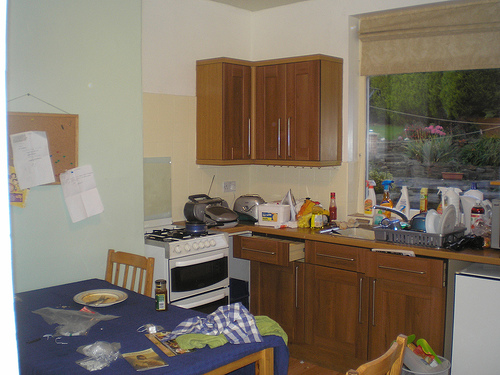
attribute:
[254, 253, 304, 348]
cupboard — wooden 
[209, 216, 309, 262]
cupboard — wooden 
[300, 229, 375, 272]
cupboard — wooden 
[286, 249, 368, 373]
cupboard — wooden 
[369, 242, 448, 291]
cupboard — wooden 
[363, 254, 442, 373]
cupboard — wooden 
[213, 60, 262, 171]
cupboard — wooden 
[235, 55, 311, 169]
cupboard — wooden 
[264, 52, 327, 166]
cupboard — wooden 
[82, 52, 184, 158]
walls — bare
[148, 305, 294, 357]
cloths — dish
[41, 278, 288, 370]
table — one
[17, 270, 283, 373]
table — one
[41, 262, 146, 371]
dishes — dirty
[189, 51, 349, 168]
cabinet — brown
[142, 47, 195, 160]
wall — kitchen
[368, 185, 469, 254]
drain — dish, full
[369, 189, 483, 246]
dishes — some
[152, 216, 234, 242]
pan — frying, small 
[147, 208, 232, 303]
oven — one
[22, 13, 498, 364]
kitchen — one, dirty , messy, cluttered 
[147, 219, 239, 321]
stove — compact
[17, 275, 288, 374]
dining table — Messy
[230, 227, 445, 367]
kitchen cabinets — wooden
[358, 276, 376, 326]
pulls — long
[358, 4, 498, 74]
shade — rolling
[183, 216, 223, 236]
pot — blue, silver, black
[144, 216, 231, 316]
range — gas